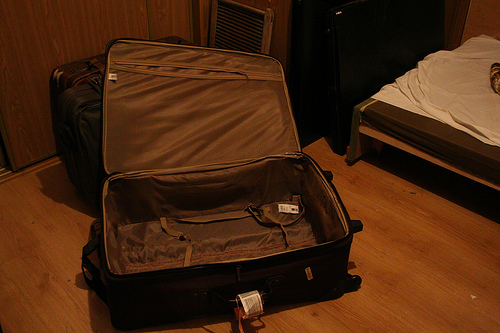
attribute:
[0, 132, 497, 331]
floor — wood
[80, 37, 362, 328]
suitcase — brown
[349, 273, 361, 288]
wheel — round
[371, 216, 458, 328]
floor — brown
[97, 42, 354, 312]
suitcase — open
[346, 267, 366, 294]
wheel — black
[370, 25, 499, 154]
sheet — white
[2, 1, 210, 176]
wall — wooden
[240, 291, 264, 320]
tag — white , black